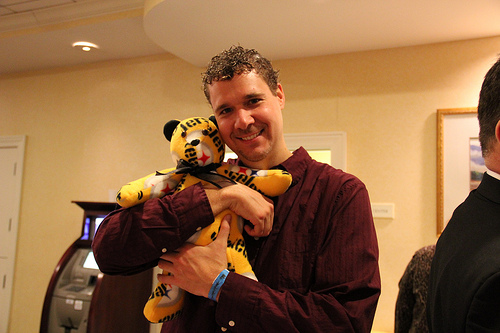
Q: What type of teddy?
A: Yellow and black.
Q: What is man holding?
A: The teddy.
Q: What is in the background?
A: ATM.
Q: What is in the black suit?
A: The man.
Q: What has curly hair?
A: The man.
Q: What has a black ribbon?
A: The steelers teddy bear.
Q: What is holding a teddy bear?
A: The man.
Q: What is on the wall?
A: The picture.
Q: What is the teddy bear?
A: Yellow.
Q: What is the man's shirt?
A: Burgundy.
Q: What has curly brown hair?
A: The man.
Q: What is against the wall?
A: Automatic teller machine.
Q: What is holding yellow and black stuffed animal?
A: The man.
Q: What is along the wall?
A: An ATM machine.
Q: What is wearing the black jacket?
A: The man on the right.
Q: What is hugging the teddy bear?
A: The smiling man.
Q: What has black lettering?
A: The gold teddy bear.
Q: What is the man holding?
A: A bear.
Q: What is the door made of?
A: Wood.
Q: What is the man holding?
A: A teddy bear.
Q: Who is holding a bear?
A: A man.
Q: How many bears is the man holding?
A: One.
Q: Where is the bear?
A: In the man's arms.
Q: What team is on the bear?
A: Steelers.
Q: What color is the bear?
A: Yellow.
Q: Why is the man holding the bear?
A: He likes it.